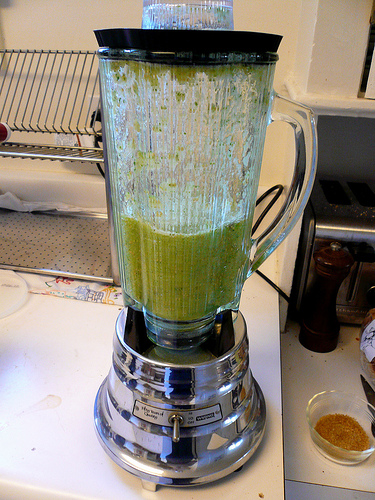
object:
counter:
[0, 263, 284, 499]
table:
[280, 272, 375, 500]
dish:
[304, 389, 375, 468]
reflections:
[158, 366, 199, 471]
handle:
[247, 89, 322, 286]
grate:
[0, 43, 104, 168]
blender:
[93, 0, 319, 489]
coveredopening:
[142, 1, 234, 28]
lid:
[0, 268, 29, 319]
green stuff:
[117, 216, 249, 320]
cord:
[249, 183, 299, 307]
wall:
[4, 5, 295, 32]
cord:
[253, 268, 300, 314]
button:
[168, 415, 185, 446]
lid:
[93, 0, 285, 57]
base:
[94, 305, 266, 489]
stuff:
[313, 413, 369, 462]